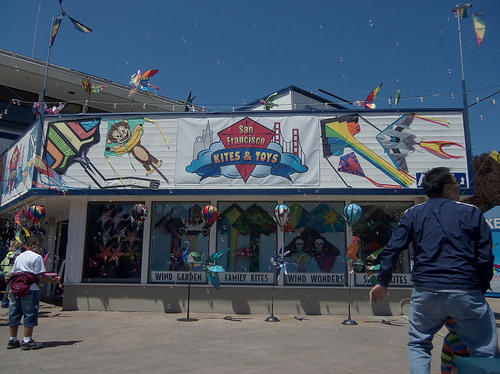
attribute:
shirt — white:
[13, 251, 50, 292]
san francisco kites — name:
[212, 115, 281, 168]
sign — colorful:
[5, 108, 476, 209]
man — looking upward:
[372, 162, 496, 373]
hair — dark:
[418, 168, 454, 199]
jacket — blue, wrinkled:
[381, 196, 493, 298]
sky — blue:
[3, 5, 500, 160]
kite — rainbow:
[318, 119, 414, 192]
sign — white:
[216, 201, 275, 286]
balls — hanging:
[25, 199, 48, 230]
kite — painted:
[377, 112, 467, 180]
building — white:
[228, 86, 352, 113]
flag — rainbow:
[470, 7, 489, 51]